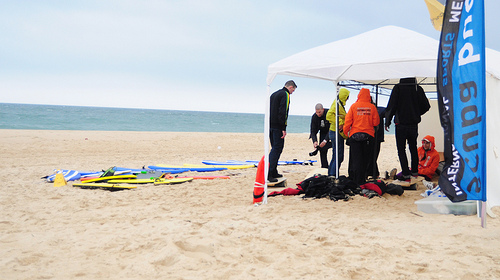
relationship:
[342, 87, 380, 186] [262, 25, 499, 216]
people under canopy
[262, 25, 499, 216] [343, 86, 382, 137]
canopy wearing an hooded jacket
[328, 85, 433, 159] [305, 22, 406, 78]
people under tent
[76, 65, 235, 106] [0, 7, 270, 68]
clouds in sky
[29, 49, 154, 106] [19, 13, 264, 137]
clouds in sky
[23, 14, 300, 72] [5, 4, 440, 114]
clouds in sky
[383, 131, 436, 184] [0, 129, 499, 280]
man on beach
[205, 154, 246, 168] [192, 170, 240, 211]
surfboard on ground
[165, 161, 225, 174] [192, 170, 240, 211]
surfboard on ground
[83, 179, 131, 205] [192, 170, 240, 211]
surfboard on ground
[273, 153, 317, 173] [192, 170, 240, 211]
surfboard on ground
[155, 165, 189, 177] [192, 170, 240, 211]
surfboard on ground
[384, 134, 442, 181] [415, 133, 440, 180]
man wearing orange jacket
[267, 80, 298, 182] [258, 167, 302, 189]
man standing on surfboard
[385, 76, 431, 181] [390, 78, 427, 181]
man wearing clothing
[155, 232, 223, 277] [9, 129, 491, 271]
tracks in sand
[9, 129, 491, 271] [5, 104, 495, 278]
sand on beach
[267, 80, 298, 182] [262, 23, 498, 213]
man standing under canopy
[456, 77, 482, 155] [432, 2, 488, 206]
text on banner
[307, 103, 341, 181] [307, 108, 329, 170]
man wearing wetsuit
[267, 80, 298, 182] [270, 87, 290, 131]
man wearing shirt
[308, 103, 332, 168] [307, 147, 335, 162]
man putting on sock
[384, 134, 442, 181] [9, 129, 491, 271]
man sitting on sand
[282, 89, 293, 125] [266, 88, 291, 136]
lines are on shirt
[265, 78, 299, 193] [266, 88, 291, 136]
man wearing shirt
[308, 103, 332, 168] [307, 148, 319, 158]
man putting on socks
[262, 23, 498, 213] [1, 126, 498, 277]
canopy on beach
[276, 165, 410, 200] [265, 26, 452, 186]
equipment under canopy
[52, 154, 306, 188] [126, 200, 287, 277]
equipment on sand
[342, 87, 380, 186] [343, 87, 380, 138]
people wearing hooded jacket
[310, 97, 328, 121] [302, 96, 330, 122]
hair on man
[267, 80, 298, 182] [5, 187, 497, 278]
man on beach